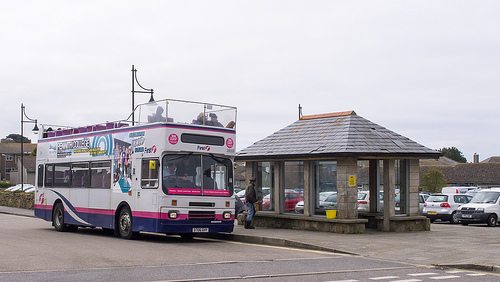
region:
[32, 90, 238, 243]
the double decker bus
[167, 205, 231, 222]
the headlights on the bus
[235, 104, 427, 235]
the enclosed bus stop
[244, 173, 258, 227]
the man standing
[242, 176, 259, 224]
the man standing near the bus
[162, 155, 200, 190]
the people on the bus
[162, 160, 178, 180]
the male bus driver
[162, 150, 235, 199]
the windshield of the bus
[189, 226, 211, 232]
the license plate on the bus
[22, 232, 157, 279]
the gray pavement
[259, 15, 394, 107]
The sky is overcast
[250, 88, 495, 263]
The building has many windows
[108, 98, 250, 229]
The bus is 2 levels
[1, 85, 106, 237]
The street lights are metal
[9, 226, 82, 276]
The road is gray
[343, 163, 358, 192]
The sign is yellow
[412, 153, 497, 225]
The cars are parked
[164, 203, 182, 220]
The lights are on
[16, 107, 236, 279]
The bus is stopped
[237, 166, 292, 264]
The person is standing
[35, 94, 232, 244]
a double decker bus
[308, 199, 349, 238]
a yellow bucket on bench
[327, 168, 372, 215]
a yellow sign on pillar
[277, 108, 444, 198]
the roof of a building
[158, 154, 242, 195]
double window on front of bus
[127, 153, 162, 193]
yellow side mirror on bus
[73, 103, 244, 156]
people riding on top of bus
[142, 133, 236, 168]
two pink and white stickers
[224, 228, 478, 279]
pull out part of parking lot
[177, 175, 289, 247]
person standing next to a bus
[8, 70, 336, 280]
a double decker bus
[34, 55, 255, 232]
a two story bus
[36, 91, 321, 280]
a passenger bus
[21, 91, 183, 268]
a bus on the road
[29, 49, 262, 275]
a bus parked on the road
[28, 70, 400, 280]
a bus at a bus stop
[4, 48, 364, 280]
a white red blue and purle bus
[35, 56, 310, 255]
a bus with seats on top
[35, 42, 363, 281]
a bus carrying people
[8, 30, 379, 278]
a bus driving people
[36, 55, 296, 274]
people on top of the bus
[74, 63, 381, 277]
a bus stopped at a bus stop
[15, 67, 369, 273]
a white bus with purple and pink stripes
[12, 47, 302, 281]
a double decker bus on road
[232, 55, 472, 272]
a covered bus stop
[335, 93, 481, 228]
vehicles that are parked